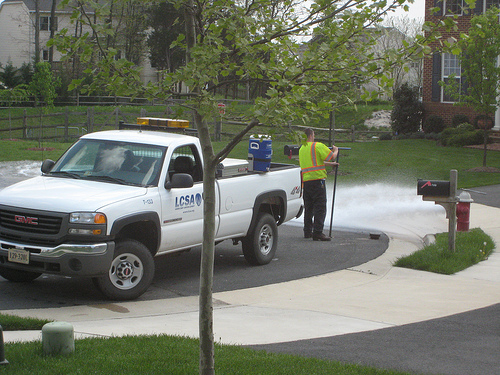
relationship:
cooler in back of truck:
[246, 135, 274, 176] [1, 116, 306, 304]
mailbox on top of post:
[416, 178, 454, 199] [421, 167, 460, 256]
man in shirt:
[297, 127, 339, 242] [299, 141, 334, 182]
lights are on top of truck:
[137, 116, 191, 131] [1, 116, 306, 304]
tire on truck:
[92, 239, 157, 303] [1, 116, 306, 304]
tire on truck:
[241, 211, 280, 268] [1, 116, 306, 304]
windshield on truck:
[44, 138, 170, 190] [1, 116, 306, 304]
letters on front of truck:
[13, 213, 39, 227] [1, 116, 306, 304]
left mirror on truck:
[164, 170, 195, 190] [1, 116, 306, 304]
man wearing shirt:
[297, 127, 339, 242] [299, 141, 334, 182]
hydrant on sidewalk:
[453, 189, 473, 235] [5, 179, 499, 347]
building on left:
[0, 0, 209, 102] [3, 1, 265, 374]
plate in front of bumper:
[7, 247, 32, 266] [0, 243, 117, 279]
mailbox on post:
[416, 178, 454, 199] [421, 167, 460, 256]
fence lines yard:
[0, 111, 396, 154] [0, 135, 499, 191]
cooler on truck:
[246, 135, 274, 176] [1, 116, 306, 304]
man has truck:
[297, 127, 339, 242] [1, 116, 306, 304]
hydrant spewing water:
[453, 189, 473, 235] [294, 182, 452, 227]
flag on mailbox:
[420, 180, 434, 189] [416, 178, 454, 199]